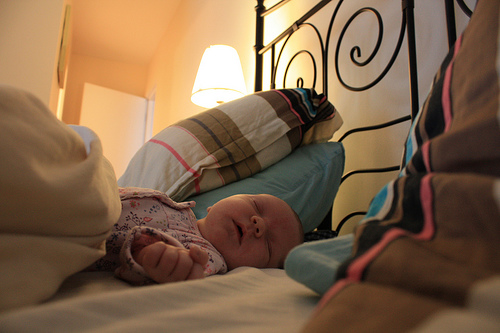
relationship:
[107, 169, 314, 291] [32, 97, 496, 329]
baby sleeping on bed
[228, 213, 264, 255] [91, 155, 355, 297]
mouth of baby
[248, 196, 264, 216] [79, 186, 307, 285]
eye of baby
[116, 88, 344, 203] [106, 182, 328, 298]
pillow behind baby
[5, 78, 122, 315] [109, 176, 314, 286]
blanket on baby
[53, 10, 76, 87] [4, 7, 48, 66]
picture hanging on wall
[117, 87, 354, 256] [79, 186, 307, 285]
pillow beside baby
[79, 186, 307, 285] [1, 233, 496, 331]
baby on bed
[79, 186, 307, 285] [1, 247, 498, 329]
baby sleeping in bed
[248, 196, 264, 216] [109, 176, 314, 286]
eye of baby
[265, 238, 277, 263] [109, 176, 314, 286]
eye of baby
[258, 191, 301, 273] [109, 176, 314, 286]
forehead of baby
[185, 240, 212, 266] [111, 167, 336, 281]
thumb of body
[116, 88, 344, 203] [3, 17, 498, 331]
pillow on bed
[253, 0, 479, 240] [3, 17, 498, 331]
black railings on bed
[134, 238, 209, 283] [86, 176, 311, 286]
hand of baby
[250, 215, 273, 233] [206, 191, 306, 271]
nose on face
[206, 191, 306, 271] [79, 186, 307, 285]
face of baby